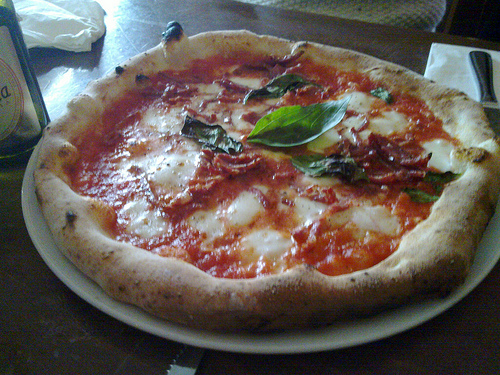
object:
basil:
[245, 92, 354, 149]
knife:
[164, 344, 206, 375]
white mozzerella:
[192, 206, 231, 244]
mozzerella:
[252, 226, 287, 250]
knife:
[468, 49, 500, 140]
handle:
[468, 50, 499, 103]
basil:
[287, 153, 371, 186]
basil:
[177, 113, 243, 156]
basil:
[241, 72, 320, 106]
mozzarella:
[360, 199, 389, 224]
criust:
[416, 81, 444, 98]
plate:
[19, 145, 499, 358]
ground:
[406, 153, 444, 184]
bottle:
[0, 0, 51, 168]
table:
[0, 0, 500, 375]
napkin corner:
[480, 47, 499, 59]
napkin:
[420, 41, 500, 104]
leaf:
[369, 86, 392, 106]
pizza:
[29, 18, 499, 335]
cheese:
[116, 168, 134, 182]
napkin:
[11, 0, 105, 54]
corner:
[427, 41, 445, 54]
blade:
[165, 344, 186, 374]